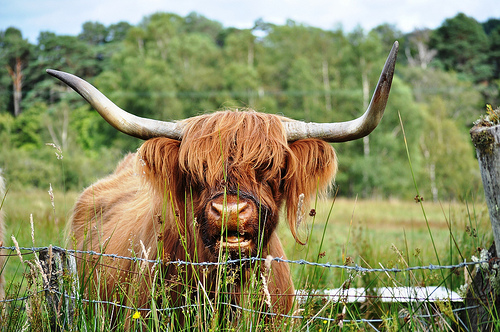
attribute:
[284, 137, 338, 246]
ear — Black 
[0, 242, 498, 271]
barbed wire — grey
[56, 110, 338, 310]
hair — brown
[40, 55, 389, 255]
cow — brown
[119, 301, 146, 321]
flower — yellow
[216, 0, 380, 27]
skies — cloudy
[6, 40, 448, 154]
horns — black, white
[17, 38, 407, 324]
cow — hairy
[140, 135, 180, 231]
ear — black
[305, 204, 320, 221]
dot — black, dangling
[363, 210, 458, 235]
dirt patch — brown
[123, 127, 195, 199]
hair — overgrown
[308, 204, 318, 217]
dot — black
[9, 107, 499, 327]
field — grass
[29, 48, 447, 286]
cow — brown